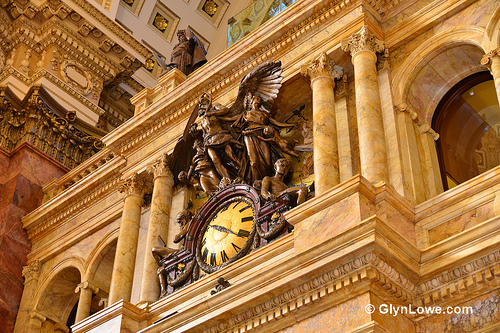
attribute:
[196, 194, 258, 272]
clock — gold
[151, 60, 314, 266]
statues — brown, bronzed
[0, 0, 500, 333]
building — gold